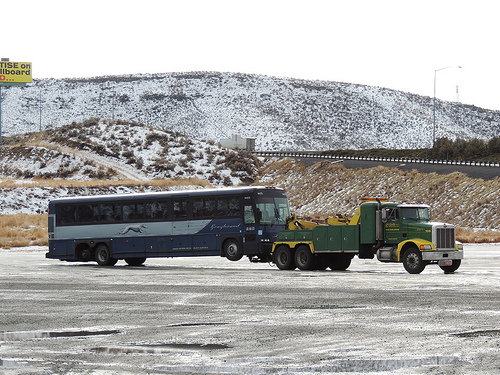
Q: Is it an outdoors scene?
A: Yes, it is outdoors.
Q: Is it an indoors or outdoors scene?
A: It is outdoors.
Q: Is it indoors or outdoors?
A: It is outdoors.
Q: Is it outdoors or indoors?
A: It is outdoors.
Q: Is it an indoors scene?
A: No, it is outdoors.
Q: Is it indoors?
A: No, it is outdoors.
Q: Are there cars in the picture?
A: No, there are no cars.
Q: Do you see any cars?
A: No, there are no cars.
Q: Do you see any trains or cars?
A: No, there are no cars or trains.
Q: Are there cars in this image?
A: No, there are no cars.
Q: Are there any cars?
A: No, there are no cars.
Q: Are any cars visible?
A: No, there are no cars.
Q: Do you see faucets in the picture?
A: No, there are no faucets.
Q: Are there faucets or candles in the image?
A: No, there are no faucets or candles.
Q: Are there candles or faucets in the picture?
A: No, there are no faucets or candles.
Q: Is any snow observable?
A: Yes, there is snow.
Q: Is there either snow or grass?
A: Yes, there is snow.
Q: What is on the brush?
A: The snow is on the brush.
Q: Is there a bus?
A: Yes, there is a bus.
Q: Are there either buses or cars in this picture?
A: Yes, there is a bus.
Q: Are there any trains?
A: No, there are no trains.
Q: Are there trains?
A: No, there are no trains.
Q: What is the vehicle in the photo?
A: The vehicle is a bus.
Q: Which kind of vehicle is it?
A: The vehicle is a bus.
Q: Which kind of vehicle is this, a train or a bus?
A: That is a bus.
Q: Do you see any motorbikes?
A: No, there are no motorbikes.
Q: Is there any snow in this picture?
A: Yes, there is snow.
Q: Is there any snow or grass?
A: Yes, there is snow.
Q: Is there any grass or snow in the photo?
A: Yes, there is snow.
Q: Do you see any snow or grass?
A: Yes, there is snow.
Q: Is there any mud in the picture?
A: No, there is no mud.